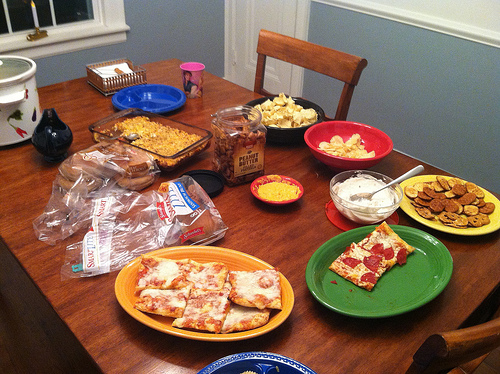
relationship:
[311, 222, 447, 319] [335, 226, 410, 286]
plate with pizza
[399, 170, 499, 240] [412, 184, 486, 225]
plate with crakers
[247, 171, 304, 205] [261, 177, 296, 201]
bowl with mustard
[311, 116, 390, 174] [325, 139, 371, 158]
bowl with chips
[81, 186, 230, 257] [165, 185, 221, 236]
bag with buns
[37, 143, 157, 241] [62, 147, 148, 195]
bag with buns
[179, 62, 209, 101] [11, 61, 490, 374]
cup on top of table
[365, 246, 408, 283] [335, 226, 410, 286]
pepperoni on top of pizza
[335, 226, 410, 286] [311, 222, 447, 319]
pizza on top of plate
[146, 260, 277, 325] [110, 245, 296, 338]
pizza on top of plate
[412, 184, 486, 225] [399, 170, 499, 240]
crakers on top of plate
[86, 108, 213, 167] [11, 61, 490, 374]
pan sitting on table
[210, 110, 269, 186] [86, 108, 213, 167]
jar next to pan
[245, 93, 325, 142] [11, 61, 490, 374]
bowl on top of a table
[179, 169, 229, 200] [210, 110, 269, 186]
lid next to container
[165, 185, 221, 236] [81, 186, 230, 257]
buns in bag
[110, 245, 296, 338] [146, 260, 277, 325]
plate with pizza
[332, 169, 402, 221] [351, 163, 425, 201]
bowl with spoon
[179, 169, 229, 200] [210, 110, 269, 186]
lid in front of container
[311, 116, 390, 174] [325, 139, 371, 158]
bowl of chips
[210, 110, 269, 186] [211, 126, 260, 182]
container with peanuts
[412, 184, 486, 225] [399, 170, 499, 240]
crakers in a plate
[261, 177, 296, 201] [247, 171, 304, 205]
mustard inside of bowl